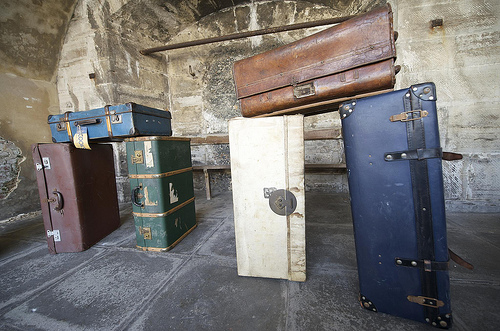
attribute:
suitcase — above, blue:
[45, 100, 174, 148]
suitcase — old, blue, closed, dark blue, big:
[337, 80, 450, 329]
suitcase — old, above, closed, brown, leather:
[227, 5, 401, 121]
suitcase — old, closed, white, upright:
[226, 112, 310, 287]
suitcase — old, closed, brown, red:
[28, 141, 124, 255]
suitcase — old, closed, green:
[122, 132, 201, 255]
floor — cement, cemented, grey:
[2, 186, 500, 329]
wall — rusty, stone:
[2, 0, 498, 225]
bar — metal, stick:
[139, 11, 358, 59]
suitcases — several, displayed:
[27, 2, 457, 330]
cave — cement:
[2, 2, 500, 328]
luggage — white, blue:
[226, 83, 457, 330]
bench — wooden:
[189, 126, 349, 203]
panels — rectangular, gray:
[2, 186, 499, 329]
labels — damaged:
[143, 138, 181, 206]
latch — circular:
[269, 188, 299, 218]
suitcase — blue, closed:
[46, 102, 172, 144]